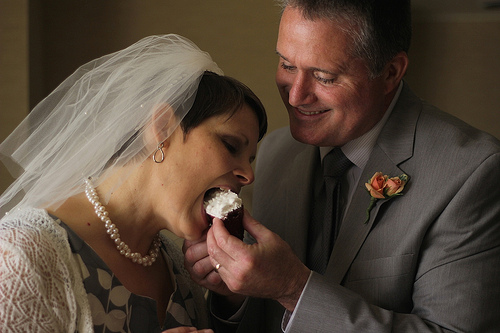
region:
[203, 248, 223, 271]
The man is wearing a wedding band.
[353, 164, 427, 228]
A flower on the man jacket.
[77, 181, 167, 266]
The woman is wearing a pearl necklace.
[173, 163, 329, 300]
The man is feeding the lady cake.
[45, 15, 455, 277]
Bride and groom in the photo.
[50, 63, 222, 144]
The woman is wearing a white veil.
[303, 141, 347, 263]
Man is wearing a gray tie.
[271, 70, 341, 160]
The man is smiling.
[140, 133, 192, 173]
The lady is wearing a earring.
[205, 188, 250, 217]
The frosting on the cake is white.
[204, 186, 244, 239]
A peice of cake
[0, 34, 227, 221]
A white wedding veil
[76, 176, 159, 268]
A white pearl necklace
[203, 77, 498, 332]
A grey suit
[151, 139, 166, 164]
Silver earrings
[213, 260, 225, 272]
A gold wedding ring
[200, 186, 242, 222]
White icing on top of cake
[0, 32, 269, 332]
A bride on wedding day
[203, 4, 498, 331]
A groom on wedding day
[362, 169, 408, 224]
An orange flower with stem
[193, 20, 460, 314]
The man is feeding the lady some cake.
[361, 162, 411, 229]
The man has a carnation on his suit.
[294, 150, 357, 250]
The man is wearing a gray tie.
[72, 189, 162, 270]
The woman is wearing pearl necklace.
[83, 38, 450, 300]
A bride and groom in the picture.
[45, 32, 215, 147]
The lady is wearing a white veil.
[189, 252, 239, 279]
The man is wearing a gold wedding band.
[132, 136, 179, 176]
The lady is wearing an earring.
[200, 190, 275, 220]
The cake is white.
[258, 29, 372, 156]
The man is smiling.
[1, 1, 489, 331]
Bride and groom sharing a piece of cake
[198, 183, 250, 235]
White icing and chocolate cake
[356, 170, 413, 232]
Two small flowers on lapel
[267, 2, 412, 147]
Groom with a smile on his face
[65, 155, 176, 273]
Bride wearing a pearl necklace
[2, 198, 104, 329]
Bride wearing a delicate white knit sweater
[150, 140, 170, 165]
Bride wearing hoop earrings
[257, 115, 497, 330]
Groom wearing a gray suit and tie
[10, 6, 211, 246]
Bride with veil on top of her head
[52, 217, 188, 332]
Flower pattern on her dress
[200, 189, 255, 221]
chocolate with white frosting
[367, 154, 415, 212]
two peach rosebuds pinned to lapel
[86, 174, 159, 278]
double strand on pearls on neck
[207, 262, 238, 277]
gold wedding band on left finger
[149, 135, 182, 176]
silver hoop earing on woman's right ear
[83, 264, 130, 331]
green dress with white leaves on top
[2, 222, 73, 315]
white crocheted sweater over dress top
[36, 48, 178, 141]
white wedding veilo with sewn in pearls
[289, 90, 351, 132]
large smile on man's face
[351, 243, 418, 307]
grey pocket on left side of man's suit